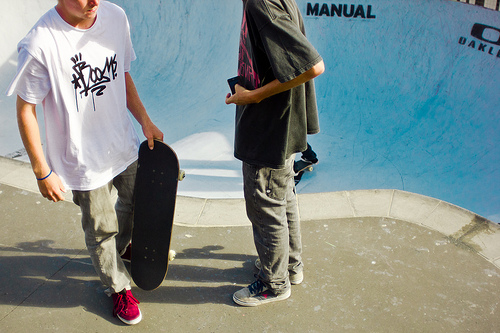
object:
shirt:
[222, 0, 327, 170]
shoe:
[102, 283, 145, 325]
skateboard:
[130, 143, 178, 291]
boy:
[222, 0, 331, 308]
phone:
[225, 75, 244, 98]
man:
[15, 2, 163, 324]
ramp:
[400, 5, 476, 191]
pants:
[236, 154, 306, 293]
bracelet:
[37, 168, 52, 181]